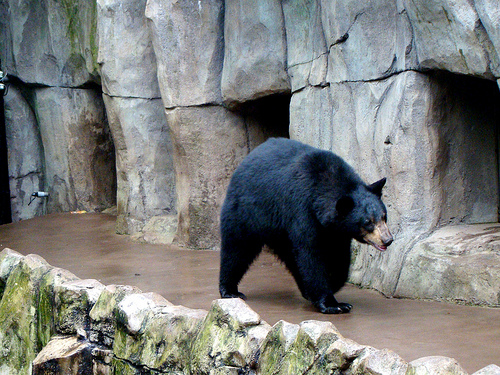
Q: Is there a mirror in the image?
A: No, there are no mirrors.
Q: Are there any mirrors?
A: No, there are no mirrors.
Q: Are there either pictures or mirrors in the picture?
A: No, there are no mirrors or pictures.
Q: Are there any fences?
A: No, there are no fences.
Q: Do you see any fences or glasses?
A: No, there are no fences or glasses.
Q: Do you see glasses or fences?
A: No, there are no fences or glasses.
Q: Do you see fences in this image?
A: No, there are no fences.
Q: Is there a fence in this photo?
A: No, there are no fences.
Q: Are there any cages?
A: No, there are no cages.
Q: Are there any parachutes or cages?
A: No, there are no cages or parachutes.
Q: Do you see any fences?
A: No, there are no fences.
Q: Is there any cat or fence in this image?
A: No, there are no fences or cats.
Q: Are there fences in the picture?
A: No, there are no fences.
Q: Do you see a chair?
A: No, there are no chairs.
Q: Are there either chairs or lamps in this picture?
A: No, there are no chairs or lamps.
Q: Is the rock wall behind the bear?
A: Yes, the wall is behind the bear.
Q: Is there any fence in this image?
A: No, there are no fences.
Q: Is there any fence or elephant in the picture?
A: No, there are no fences or elephants.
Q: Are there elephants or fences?
A: No, there are no fences or elephants.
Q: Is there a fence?
A: No, there are no fences.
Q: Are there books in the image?
A: No, there are no books.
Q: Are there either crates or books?
A: No, there are no books or crates.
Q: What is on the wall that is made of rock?
A: The moss is on the wall.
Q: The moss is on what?
A: The moss is on the wall.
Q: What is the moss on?
A: The moss is on the wall.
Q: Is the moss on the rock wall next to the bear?
A: Yes, the moss is on the wall.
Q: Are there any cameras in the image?
A: Yes, there is a camera.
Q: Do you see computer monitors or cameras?
A: Yes, there is a camera.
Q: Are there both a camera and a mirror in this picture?
A: No, there is a camera but no mirrors.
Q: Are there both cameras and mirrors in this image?
A: No, there is a camera but no mirrors.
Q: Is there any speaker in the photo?
A: No, there are no speakers.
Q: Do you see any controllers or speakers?
A: No, there are no speakers or controllers.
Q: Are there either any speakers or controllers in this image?
A: No, there are no speakers or controllers.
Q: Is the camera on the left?
A: Yes, the camera is on the left of the image.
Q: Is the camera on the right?
A: No, the camera is on the left of the image.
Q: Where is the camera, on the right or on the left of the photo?
A: The camera is on the left of the image.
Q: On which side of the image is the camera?
A: The camera is on the left of the image.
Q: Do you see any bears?
A: Yes, there is a bear.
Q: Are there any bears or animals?
A: Yes, there is a bear.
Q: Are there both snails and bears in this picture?
A: No, there is a bear but no snails.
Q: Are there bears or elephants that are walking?
A: Yes, the bear is walking.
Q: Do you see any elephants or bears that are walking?
A: Yes, the bear is walking.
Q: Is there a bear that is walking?
A: Yes, there is a bear that is walking.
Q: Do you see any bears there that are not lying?
A: Yes, there is a bear that is walking .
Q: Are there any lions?
A: No, there are no lions.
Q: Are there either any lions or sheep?
A: No, there are no lions or sheep.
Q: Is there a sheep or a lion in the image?
A: No, there are no lions or sheep.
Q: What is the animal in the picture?
A: The animal is a bear.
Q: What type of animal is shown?
A: The animal is a bear.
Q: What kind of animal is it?
A: The animal is a bear.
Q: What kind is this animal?
A: This is a bear.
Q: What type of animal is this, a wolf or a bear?
A: This is a bear.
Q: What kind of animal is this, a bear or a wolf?
A: This is a bear.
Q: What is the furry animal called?
A: The animal is a bear.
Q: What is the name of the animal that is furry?
A: The animal is a bear.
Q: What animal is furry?
A: The animal is a bear.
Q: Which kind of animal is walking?
A: The animal is a bear.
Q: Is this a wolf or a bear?
A: This is a bear.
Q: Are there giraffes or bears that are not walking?
A: No, there is a bear but it is walking.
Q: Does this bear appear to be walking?
A: Yes, the bear is walking.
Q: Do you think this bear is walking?
A: Yes, the bear is walking.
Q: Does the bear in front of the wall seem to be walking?
A: Yes, the bear is walking.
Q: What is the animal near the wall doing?
A: The bear is walking.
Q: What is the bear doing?
A: The bear is walking.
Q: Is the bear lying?
A: No, the bear is walking.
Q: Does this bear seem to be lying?
A: No, the bear is walking.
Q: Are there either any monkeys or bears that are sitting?
A: No, there is a bear but it is walking.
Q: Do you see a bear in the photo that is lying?
A: No, there is a bear but it is walking.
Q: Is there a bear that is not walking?
A: No, there is a bear but it is walking.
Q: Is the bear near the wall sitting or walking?
A: The bear is walking.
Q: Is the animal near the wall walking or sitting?
A: The bear is walking.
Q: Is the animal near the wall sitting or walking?
A: The bear is walking.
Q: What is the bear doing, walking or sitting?
A: The bear is walking.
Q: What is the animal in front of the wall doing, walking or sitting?
A: The bear is walking.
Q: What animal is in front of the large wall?
A: The bear is in front of the wall.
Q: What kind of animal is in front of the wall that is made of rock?
A: The animal is a bear.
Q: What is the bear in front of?
A: The bear is in front of the wall.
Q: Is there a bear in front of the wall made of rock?
A: Yes, there is a bear in front of the wall.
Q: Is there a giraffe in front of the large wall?
A: No, there is a bear in front of the wall.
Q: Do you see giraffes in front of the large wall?
A: No, there is a bear in front of the wall.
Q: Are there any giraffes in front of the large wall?
A: No, there is a bear in front of the wall.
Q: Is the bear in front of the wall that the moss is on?
A: Yes, the bear is in front of the wall.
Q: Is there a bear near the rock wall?
A: Yes, there is a bear near the wall.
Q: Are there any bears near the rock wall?
A: Yes, there is a bear near the wall.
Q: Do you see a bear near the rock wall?
A: Yes, there is a bear near the wall.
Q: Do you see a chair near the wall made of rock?
A: No, there is a bear near the wall.